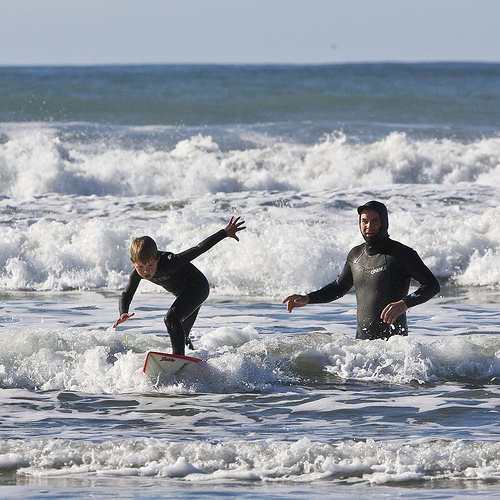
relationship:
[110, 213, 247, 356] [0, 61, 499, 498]
boy surfing in ocean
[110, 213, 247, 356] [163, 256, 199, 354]
boy wearing wetsuit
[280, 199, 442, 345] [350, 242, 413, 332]
adult in wetsuit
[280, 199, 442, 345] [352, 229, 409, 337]
adult wearing wetsuit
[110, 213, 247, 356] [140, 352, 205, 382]
boy on surfboard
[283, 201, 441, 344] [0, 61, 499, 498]
adult in ocean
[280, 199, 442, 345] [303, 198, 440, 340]
adult in wet suit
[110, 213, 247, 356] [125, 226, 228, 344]
boy in wetsuit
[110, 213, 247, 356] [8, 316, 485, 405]
boy surfing wave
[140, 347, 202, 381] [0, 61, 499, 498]
surfboard out of ocean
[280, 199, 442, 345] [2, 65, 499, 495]
adult in ocean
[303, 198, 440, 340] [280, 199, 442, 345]
wet suit of adult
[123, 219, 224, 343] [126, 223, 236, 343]
wetsuit of boy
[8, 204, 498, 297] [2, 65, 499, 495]
wave in ocean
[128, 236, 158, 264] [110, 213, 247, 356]
hair of boy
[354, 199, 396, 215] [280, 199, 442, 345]
hat of adult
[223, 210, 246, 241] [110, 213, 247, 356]
hand of boy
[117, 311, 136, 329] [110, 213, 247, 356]
hand of boy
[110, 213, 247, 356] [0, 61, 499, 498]
boy in ocean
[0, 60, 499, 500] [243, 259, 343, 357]
body of water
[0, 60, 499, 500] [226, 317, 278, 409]
body of water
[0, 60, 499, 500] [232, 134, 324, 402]
body of water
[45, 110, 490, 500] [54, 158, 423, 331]
body of water with wave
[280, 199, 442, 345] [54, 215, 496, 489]
adult standing in water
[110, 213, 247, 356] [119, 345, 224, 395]
boy riding surfboard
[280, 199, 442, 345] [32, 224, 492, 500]
adult in water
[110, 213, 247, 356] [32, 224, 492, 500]
boy in water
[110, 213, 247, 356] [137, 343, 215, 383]
boy standing on surfboard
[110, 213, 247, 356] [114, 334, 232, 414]
boy  surfing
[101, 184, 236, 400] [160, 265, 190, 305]
boy wearing wetsuit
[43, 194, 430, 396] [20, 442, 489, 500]
wave  splashing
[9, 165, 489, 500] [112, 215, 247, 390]
wave in surfing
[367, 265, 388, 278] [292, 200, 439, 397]
letter on wetsuit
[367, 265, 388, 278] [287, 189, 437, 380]
letter on wetsuit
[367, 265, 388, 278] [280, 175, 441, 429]
letter on wetsuit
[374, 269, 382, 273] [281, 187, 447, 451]
letter on wetsuit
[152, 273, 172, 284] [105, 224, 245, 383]
letter on wetsuit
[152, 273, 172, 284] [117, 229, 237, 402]
letter on wetsuit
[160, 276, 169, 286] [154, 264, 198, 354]
letter on a wetsuit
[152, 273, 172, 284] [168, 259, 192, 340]
letter on a wetsuit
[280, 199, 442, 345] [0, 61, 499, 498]
adult standing in ocean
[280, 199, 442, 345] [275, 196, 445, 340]
adult wearing wet suit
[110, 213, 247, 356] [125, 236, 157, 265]
boy with hair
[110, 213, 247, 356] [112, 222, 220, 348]
boy wearing wet suit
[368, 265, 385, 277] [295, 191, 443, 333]
logo on wet suit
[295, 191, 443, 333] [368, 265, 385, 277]
wet suit with logo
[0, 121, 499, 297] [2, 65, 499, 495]
wave crashing in ocean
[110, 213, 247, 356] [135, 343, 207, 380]
boy on surfboard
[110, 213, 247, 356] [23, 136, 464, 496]
boy in water